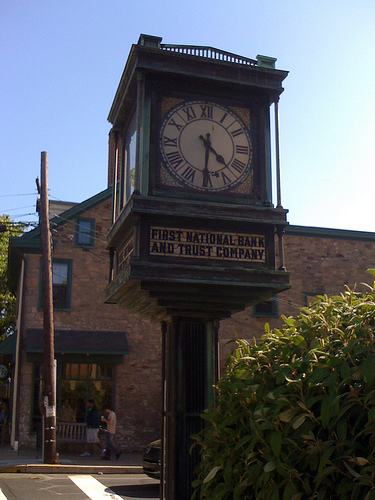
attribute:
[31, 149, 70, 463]
pole — brown, tall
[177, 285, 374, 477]
hedge — green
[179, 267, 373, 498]
bush — green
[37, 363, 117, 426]
window — large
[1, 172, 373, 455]
building — stone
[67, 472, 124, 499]
line — white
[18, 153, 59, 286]
pole — wooden, large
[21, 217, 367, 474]
building — large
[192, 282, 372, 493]
bush — green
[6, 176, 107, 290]
trim — green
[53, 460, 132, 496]
line — white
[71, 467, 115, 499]
stripe — white, wide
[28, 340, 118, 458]
window — large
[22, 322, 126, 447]
window — large